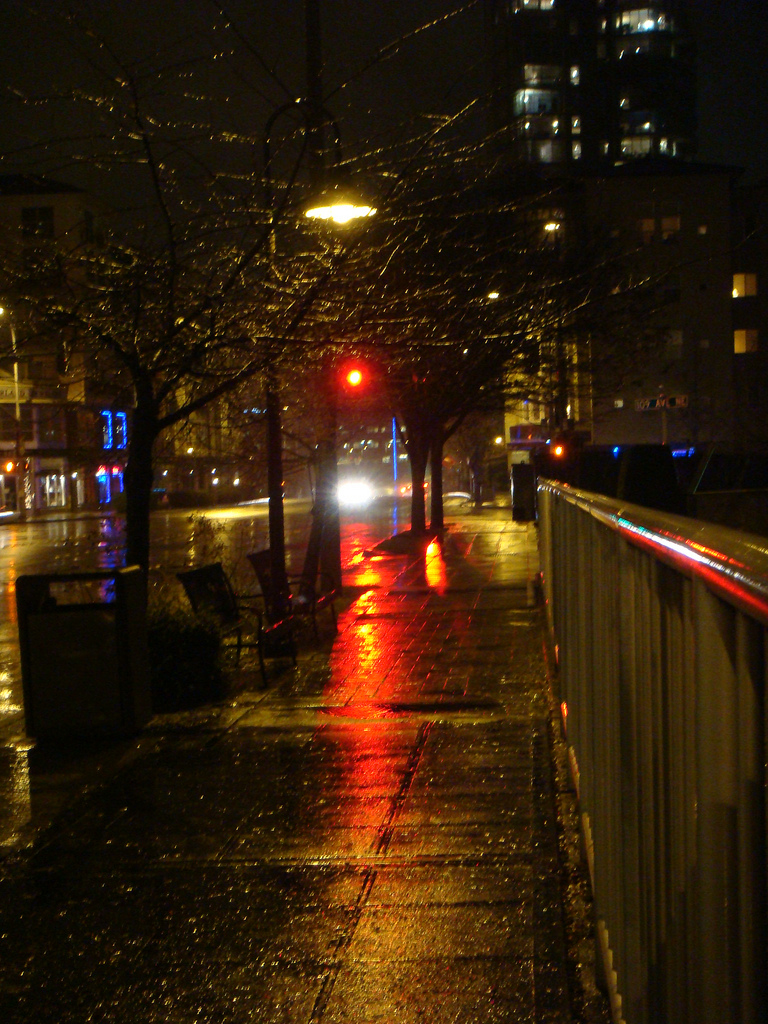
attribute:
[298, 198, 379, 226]
light — yellow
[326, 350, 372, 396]
traffic signal — red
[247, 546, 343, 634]
bench — wooden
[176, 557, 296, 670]
bench — wooden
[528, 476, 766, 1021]
fence — wood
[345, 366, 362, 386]
stoplight — red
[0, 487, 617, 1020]
sidewalk — wet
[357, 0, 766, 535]
building — tall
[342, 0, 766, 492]
building — BIG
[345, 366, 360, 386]
light — RED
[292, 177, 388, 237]
light — on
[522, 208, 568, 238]
light — on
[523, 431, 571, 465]
light — on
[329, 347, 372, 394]
light — red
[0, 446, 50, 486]
sign — pedestrian